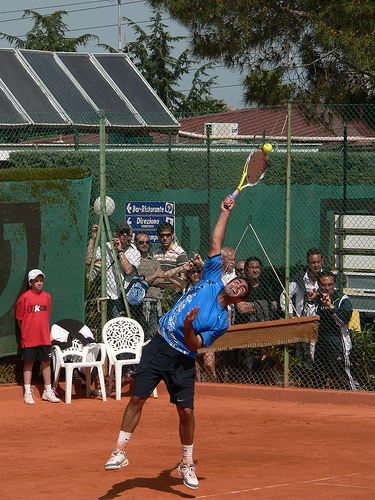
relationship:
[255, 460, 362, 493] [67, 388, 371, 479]
line on court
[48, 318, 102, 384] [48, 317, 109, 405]
jacket on chair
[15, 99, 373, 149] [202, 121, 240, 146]
roof of air conditioner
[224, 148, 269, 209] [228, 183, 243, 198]
racket of handle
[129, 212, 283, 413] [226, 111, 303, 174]
man with ball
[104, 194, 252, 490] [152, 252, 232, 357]
man with shirt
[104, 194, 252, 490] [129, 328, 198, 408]
man with shorts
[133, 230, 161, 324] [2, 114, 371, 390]
person on fence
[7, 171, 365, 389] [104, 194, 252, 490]
wall behind man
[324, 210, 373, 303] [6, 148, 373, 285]
window inside wall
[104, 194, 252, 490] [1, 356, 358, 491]
man on court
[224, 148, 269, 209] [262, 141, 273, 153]
racket hits ball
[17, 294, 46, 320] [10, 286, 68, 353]
letter on shirt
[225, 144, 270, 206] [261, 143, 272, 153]
racket hitting ball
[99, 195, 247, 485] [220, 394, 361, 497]
man off ground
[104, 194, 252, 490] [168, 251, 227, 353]
man wearing shirt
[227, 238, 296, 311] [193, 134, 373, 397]
man behind fence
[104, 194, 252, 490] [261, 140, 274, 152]
man hitting ball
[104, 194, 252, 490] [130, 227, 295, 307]
man outside fence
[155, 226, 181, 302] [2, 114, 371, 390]
man outside fence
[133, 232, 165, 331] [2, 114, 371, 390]
man outside fence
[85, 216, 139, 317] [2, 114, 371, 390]
man outside fence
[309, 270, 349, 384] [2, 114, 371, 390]
man outside fence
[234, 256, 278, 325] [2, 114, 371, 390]
man outside fence